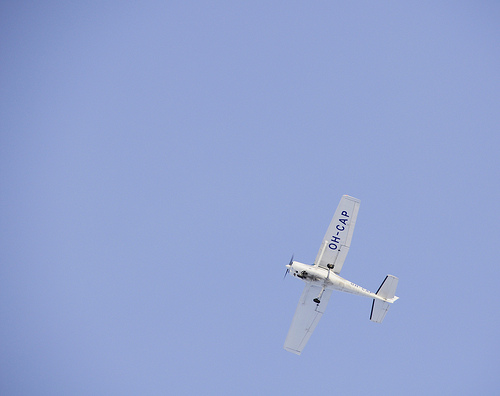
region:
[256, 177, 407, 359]
A small white plane flying across a blue sky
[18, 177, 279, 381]
A clear blue sky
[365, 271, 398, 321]
The tail of a small plane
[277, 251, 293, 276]
Propellers on a plane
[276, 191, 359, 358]
Wings of a white plane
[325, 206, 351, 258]
Blue letters on a plane's wing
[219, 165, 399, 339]
a plane flying in the air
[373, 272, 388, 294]
the black on the tail of the plane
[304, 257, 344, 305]
the wheels of the plane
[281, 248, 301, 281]
the propeller of the plane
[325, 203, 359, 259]
the number of the plane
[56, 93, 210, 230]
the clear blue sky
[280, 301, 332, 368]
the wing of the plane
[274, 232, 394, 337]
the bottom of the air plane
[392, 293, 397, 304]
the tail of the plane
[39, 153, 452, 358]
plane in the clear blue sky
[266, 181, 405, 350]
white plane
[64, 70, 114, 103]
white clouds in blue sky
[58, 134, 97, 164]
white clouds in blue sky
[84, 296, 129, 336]
white clouds in blue sky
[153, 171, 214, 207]
white clouds in blue sky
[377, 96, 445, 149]
white clouds in blue sky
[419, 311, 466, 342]
white clouds in blue sky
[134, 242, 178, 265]
white clouds in blue sky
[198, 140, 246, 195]
white clouds in blue sky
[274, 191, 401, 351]
white plane in air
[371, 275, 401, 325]
white tail on plane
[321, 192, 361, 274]
white wing on plane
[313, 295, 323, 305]
black tire on plane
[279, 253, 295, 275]
propeller on planes nose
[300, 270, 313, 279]
tire on bottom of plane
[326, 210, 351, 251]
blue letters on plane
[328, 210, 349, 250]
letters on plane wing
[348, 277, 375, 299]
letters on air plane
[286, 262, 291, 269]
white nose on plane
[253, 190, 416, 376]
the plane is white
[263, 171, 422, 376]
the plane is white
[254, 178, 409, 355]
the plane is white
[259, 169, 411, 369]
the plane is white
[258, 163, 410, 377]
the plane is white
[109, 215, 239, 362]
the sky is clear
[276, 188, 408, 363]
white airplane in sky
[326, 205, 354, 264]
blue letters on plane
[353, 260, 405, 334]
tail of airplane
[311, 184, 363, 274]
right wing of airplane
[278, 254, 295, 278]
propellor is turning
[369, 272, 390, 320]
blue stripe on the tail of the plane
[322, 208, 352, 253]
OH-CAP written in blue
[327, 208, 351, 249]
OH-CAP on plane wing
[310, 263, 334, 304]
wheels on the plane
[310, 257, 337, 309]
airplane has two wheels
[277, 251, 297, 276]
propeller is blue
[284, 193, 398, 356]
airplane is white